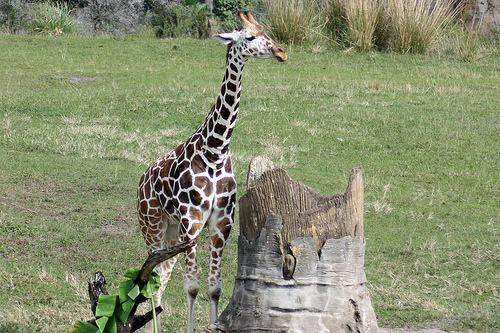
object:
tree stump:
[88, 239, 197, 333]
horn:
[238, 11, 258, 26]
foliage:
[28, 6, 72, 35]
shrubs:
[0, 0, 500, 63]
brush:
[219, 0, 500, 62]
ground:
[0, 32, 499, 333]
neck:
[195, 55, 245, 150]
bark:
[205, 215, 378, 333]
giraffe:
[136, 11, 288, 333]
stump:
[201, 151, 378, 333]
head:
[213, 11, 287, 62]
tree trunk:
[202, 156, 378, 333]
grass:
[1, 29, 500, 333]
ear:
[212, 33, 237, 41]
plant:
[70, 268, 161, 333]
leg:
[207, 225, 232, 324]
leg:
[176, 232, 198, 327]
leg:
[155, 238, 180, 325]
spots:
[174, 148, 219, 179]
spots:
[225, 74, 236, 107]